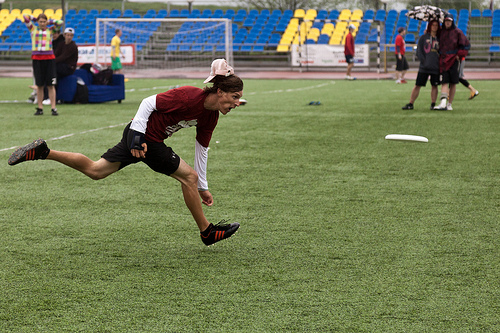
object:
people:
[13, 10, 481, 255]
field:
[0, 21, 500, 331]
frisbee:
[383, 127, 430, 148]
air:
[253, 86, 381, 223]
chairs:
[254, 79, 265, 86]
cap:
[203, 59, 234, 84]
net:
[95, 19, 228, 75]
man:
[8, 58, 246, 246]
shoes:
[198, 220, 241, 246]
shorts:
[99, 125, 183, 177]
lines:
[209, 130, 494, 146]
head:
[216, 75, 244, 117]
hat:
[200, 55, 234, 84]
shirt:
[130, 86, 219, 192]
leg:
[8, 135, 137, 181]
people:
[392, 8, 481, 117]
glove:
[126, 128, 146, 150]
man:
[108, 27, 128, 84]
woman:
[25, 41, 67, 143]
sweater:
[24, 40, 66, 78]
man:
[434, 16, 471, 111]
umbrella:
[404, 6, 447, 23]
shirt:
[106, 34, 122, 57]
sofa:
[57, 63, 127, 104]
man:
[60, 28, 85, 83]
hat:
[89, 62, 109, 76]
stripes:
[7, 140, 50, 167]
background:
[0, 1, 500, 85]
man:
[342, 23, 357, 81]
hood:
[418, 17, 440, 41]